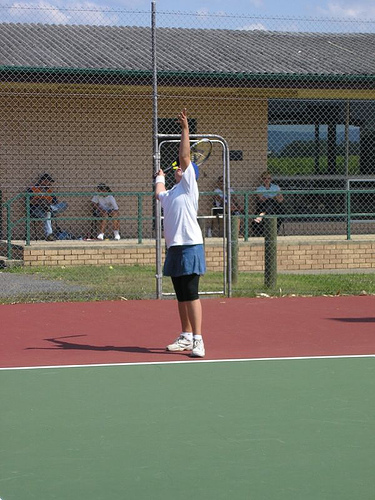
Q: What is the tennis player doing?
A: Serving.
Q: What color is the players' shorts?
A: Blue.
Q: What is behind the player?
A: Spectators.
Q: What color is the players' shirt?
A: White.